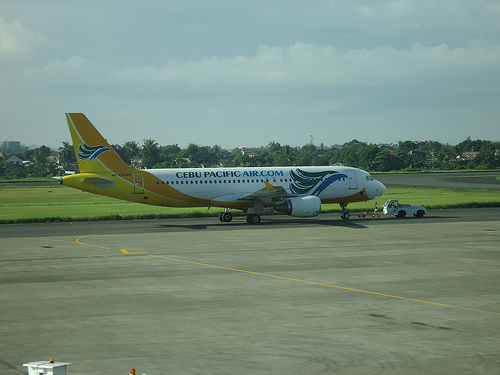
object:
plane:
[55, 110, 386, 224]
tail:
[63, 112, 136, 175]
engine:
[272, 193, 323, 216]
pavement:
[1, 207, 499, 373]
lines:
[146, 254, 500, 315]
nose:
[373, 178, 387, 199]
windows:
[273, 178, 276, 182]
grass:
[0, 171, 499, 221]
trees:
[371, 147, 402, 170]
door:
[345, 166, 358, 190]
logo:
[78, 142, 109, 162]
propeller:
[49, 172, 61, 184]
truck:
[384, 199, 427, 219]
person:
[371, 202, 380, 218]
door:
[196, 190, 215, 205]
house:
[6, 154, 20, 165]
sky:
[0, 0, 499, 151]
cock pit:
[356, 169, 374, 183]